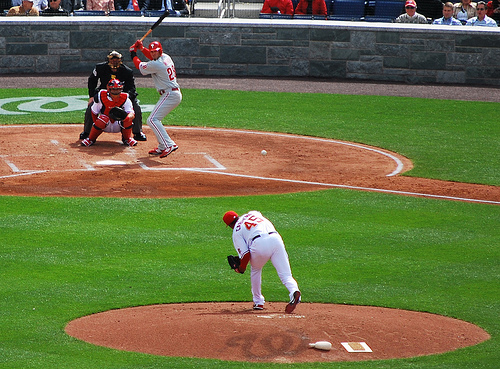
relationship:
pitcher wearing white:
[222, 211, 303, 312] [262, 223, 270, 230]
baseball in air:
[259, 149, 270, 156] [233, 139, 249, 155]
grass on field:
[445, 101, 489, 141] [397, 161, 497, 361]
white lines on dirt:
[212, 158, 220, 165] [290, 144, 327, 172]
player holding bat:
[139, 42, 183, 158] [143, 8, 172, 36]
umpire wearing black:
[99, 50, 128, 71] [99, 67, 108, 73]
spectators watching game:
[403, 1, 492, 22] [71, 20, 314, 324]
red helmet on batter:
[156, 42, 159, 49] [139, 42, 183, 158]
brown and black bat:
[143, 29, 153, 38] [143, 8, 172, 36]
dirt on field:
[290, 144, 327, 172] [397, 161, 497, 361]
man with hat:
[222, 211, 303, 312] [224, 211, 237, 223]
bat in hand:
[143, 8, 172, 36] [134, 39, 142, 48]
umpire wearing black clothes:
[99, 50, 128, 71] [93, 68, 133, 76]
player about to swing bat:
[139, 42, 183, 158] [143, 8, 172, 36]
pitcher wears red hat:
[222, 211, 303, 312] [224, 211, 237, 223]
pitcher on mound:
[222, 211, 303, 312] [216, 309, 318, 331]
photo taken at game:
[0, 5, 490, 355] [71, 20, 314, 324]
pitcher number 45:
[222, 211, 303, 312] [245, 215, 264, 231]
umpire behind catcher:
[99, 50, 128, 71] [92, 79, 135, 146]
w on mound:
[230, 326, 308, 360] [216, 309, 318, 331]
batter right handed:
[139, 42, 183, 158] [128, 44, 138, 59]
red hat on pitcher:
[224, 211, 237, 223] [222, 211, 303, 312]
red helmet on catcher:
[156, 42, 159, 49] [92, 79, 135, 146]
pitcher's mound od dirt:
[222, 211, 303, 312] [290, 144, 327, 172]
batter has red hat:
[139, 42, 183, 158] [150, 41, 161, 51]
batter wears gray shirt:
[139, 42, 183, 158] [147, 60, 179, 88]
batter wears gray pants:
[139, 42, 183, 158] [152, 92, 183, 146]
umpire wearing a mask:
[99, 50, 128, 71] [109, 56, 123, 67]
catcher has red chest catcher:
[92, 79, 135, 146] [80, 79, 139, 148]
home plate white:
[88, 145, 133, 182] [262, 223, 270, 230]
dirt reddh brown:
[290, 144, 327, 172] [143, 29, 153, 38]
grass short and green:
[445, 101, 489, 141] [326, 103, 367, 126]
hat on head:
[221, 203, 241, 216] [221, 195, 256, 245]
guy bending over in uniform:
[222, 211, 303, 312] [212, 196, 312, 321]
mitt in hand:
[109, 106, 126, 120] [220, 253, 251, 275]